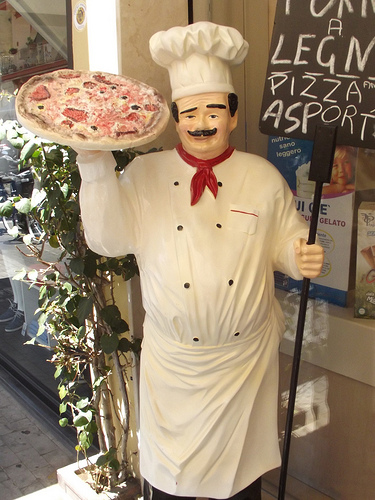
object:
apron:
[138, 295, 285, 498]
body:
[70, 19, 325, 499]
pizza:
[14, 66, 171, 152]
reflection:
[280, 284, 332, 439]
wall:
[116, 0, 143, 69]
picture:
[289, 161, 354, 308]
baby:
[320, 144, 356, 200]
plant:
[0, 120, 137, 492]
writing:
[259, 0, 374, 146]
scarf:
[174, 144, 234, 207]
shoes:
[3, 307, 26, 334]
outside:
[0, 0, 373, 499]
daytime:
[0, 1, 374, 500]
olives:
[38, 104, 44, 109]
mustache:
[186, 128, 218, 137]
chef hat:
[147, 20, 249, 105]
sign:
[257, 0, 373, 320]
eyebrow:
[178, 104, 199, 116]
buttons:
[173, 181, 180, 187]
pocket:
[228, 207, 259, 219]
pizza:
[264, 72, 363, 104]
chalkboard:
[258, 0, 375, 150]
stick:
[277, 181, 323, 500]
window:
[0, 0, 97, 454]